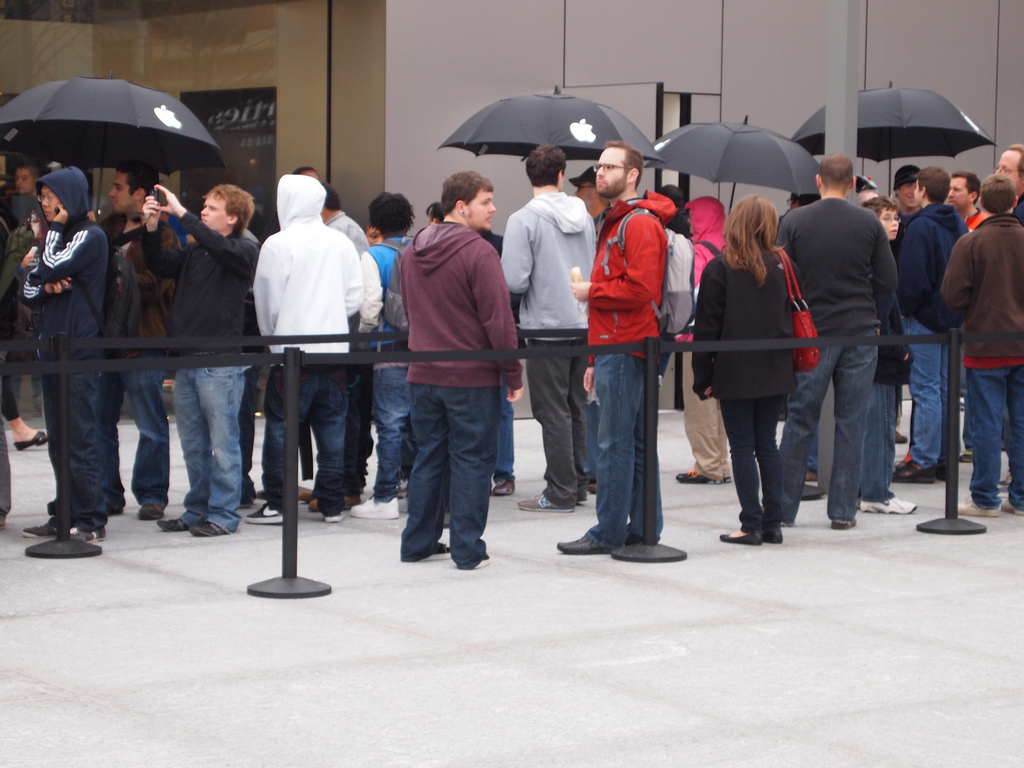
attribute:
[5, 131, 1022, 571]
people — standing, waiting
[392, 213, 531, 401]
hoodie — purple, dark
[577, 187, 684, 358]
coat — red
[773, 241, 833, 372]
purse — red, bright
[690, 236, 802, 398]
coat — black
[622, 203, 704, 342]
backpack — grey, white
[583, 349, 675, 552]
jeans — blue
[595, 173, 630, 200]
beard — trimmed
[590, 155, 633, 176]
glasses — small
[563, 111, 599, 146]
logo — white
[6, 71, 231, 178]
umbrella — black, dark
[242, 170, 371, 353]
jacket — white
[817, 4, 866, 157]
pole — grey, tall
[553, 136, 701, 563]
man — looking, staring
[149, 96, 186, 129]
logo — white